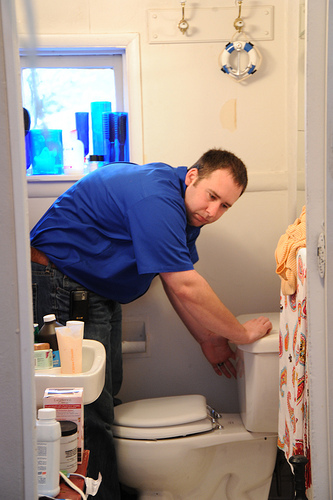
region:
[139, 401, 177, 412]
toilet lid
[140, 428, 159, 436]
the toilet seat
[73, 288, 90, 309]
a phone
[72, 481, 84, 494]
a white cord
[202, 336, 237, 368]
the mans hand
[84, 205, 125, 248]
man is wearing a blue shirt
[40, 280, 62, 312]
man is wearing blue jeans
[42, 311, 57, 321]
a white cap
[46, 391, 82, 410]
a pink box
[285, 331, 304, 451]
a towel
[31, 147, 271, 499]
A man inside a bathroom.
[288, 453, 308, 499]
The handle of a plunger.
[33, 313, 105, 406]
The sink is full of hygienic products.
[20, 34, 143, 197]
Several items are lined up along the windowsill.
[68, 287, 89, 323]
A cellphone in a small black case.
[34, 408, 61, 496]
A white bottle with a label on the back.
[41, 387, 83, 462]
An unopened pink box.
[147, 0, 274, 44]
A panel with two hooks attached.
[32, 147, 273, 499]
The man is wearing a blue shirt and jeans.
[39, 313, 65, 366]
A brown bottle with a small white lid.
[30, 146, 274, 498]
man wearing bright blue shirt and jeans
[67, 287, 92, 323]
cell phone in holster hanging on man's pocket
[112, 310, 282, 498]
white toilet with seat and lid down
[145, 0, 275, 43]
rack on wall for hanging towels or clothing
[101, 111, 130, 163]
hairbrushes in blue container on windowsill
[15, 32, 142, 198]
small bathroom window with objects on sill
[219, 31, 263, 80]
tiny blue and white life preserver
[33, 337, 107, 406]
white pedestal sink containing bottles and tubes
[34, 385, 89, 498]
three containers sitting on wooden surface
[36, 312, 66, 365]
brown bottle with blue label in sink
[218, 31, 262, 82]
a small blue and white life preserver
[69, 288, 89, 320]
a black cell phone hanging from a pocket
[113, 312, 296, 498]
a white toilet stoll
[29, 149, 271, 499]
a man with brown hair wearing a blue shirt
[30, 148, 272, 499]
a brown haired man wearing a wedding ring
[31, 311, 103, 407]
products stacked into a white sink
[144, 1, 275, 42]
a coat rack with two hooks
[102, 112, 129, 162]
a blue jar holding two hair brushes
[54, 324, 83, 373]
container of orange lotion in the sink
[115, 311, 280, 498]
toilet with a white seat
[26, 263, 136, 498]
Man wearing pants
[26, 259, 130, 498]
Man is wearing pants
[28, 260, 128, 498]
Man wearing blue pants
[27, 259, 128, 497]
Man is wearing blue pants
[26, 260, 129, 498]
Man wearing jeans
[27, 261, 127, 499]
Man is wearing jeans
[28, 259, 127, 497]
Man wearing blue jeans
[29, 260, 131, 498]
Man is wearing blue jeans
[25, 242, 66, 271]
Man wearing a brown belt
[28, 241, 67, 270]
Man is wearing a brown belt